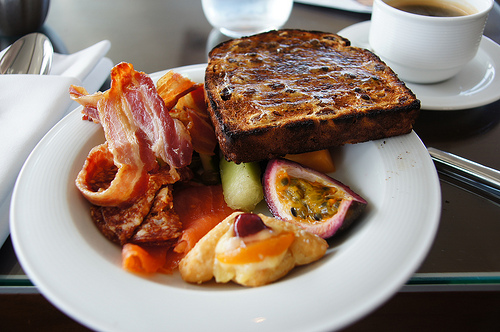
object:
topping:
[203, 30, 418, 162]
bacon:
[69, 60, 192, 208]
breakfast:
[15, 1, 498, 326]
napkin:
[0, 35, 119, 254]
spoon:
[0, 30, 52, 77]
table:
[2, 5, 496, 322]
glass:
[410, 180, 497, 297]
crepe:
[183, 210, 329, 288]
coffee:
[384, 2, 476, 22]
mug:
[364, 3, 492, 85]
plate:
[8, 57, 445, 331]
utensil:
[427, 139, 498, 205]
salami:
[78, 164, 184, 247]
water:
[199, 0, 293, 40]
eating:
[67, 30, 421, 287]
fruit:
[253, 154, 366, 240]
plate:
[335, 17, 498, 112]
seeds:
[285, 184, 306, 201]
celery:
[215, 137, 264, 210]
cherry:
[233, 211, 265, 238]